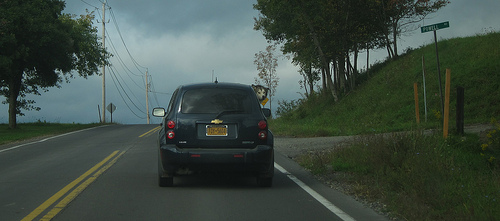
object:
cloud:
[164, 35, 227, 61]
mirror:
[152, 107, 166, 117]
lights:
[167, 121, 268, 140]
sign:
[420, 21, 451, 34]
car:
[152, 77, 272, 186]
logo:
[211, 119, 224, 124]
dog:
[251, 84, 269, 100]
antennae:
[215, 77, 219, 84]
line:
[19, 146, 127, 221]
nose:
[262, 95, 265, 97]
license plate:
[208, 128, 227, 135]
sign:
[106, 102, 116, 113]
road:
[0, 123, 388, 221]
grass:
[302, 128, 498, 220]